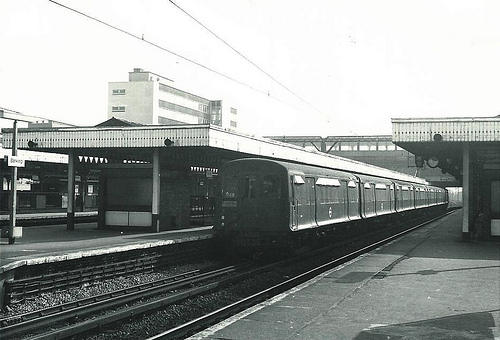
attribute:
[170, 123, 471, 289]
train — dark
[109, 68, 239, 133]
building — large, white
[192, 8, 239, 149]
cables — electrical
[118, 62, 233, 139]
rise — high